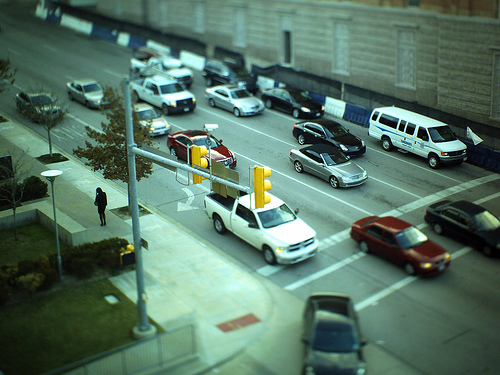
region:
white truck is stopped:
[208, 187, 317, 275]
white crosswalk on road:
[306, 184, 488, 325]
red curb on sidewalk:
[214, 319, 258, 347]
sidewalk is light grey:
[152, 254, 252, 279]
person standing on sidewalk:
[82, 183, 108, 223]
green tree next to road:
[92, 96, 159, 238]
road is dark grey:
[231, 130, 277, 194]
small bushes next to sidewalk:
[0, 231, 128, 288]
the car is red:
[353, 211, 445, 277]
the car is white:
[221, 195, 322, 271]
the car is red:
[162, 127, 238, 171]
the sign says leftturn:
[166, 183, 202, 221]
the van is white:
[366, 107, 467, 172]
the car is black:
[295, 118, 360, 149]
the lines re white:
[324, 232, 393, 307]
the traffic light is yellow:
[251, 161, 281, 213]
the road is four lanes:
[135, 102, 363, 189]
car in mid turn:
[283, 286, 379, 373]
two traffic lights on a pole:
[171, 130, 280, 217]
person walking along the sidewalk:
[88, 183, 113, 228]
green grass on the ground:
[4, 213, 174, 374]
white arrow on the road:
[171, 180, 203, 217]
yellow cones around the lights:
[261, 165, 275, 209]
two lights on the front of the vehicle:
[415, 252, 452, 270]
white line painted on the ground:
[346, 220, 497, 311]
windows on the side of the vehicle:
[367, 110, 432, 143]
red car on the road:
[162, 124, 246, 174]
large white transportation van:
[367, 100, 471, 170]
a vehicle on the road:
[302, 137, 352, 194]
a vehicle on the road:
[285, 283, 370, 373]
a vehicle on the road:
[347, 208, 432, 277]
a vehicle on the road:
[419, 186, 499, 268]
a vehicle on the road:
[224, 166, 309, 261]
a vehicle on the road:
[364, 103, 476, 180]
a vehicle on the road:
[163, 129, 238, 191]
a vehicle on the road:
[18, 81, 64, 123]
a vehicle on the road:
[70, 71, 107, 123]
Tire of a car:
[353, 237, 370, 255]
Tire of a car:
[328, 173, 341, 190]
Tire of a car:
[290, 160, 305, 173]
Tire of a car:
[206, 93, 216, 111]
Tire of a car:
[231, 105, 241, 117]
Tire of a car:
[431, 221, 445, 236]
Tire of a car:
[478, 240, 493, 259]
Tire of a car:
[403, 261, 418, 279]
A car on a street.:
[348, 208, 451, 280]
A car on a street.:
[206, 180, 323, 270]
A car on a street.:
[291, 280, 359, 368]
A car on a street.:
[292, 139, 374, 192]